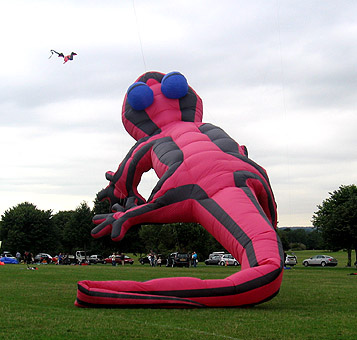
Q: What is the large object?
A: Lizard.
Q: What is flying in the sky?
A: Kite.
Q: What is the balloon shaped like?
A: A large lizard.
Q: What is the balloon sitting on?
A: The grass.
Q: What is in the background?
A: Cars.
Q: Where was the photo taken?
A: Field.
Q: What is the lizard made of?
A: Balloon.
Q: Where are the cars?
A: Field.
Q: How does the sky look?
A: Cloudy.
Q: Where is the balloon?
A: On grass.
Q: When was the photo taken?
A: During a celebration.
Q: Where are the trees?
A: Background.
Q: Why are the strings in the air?
A: Flying kites.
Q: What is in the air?
A: Kites.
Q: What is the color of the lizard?
A: Black and red.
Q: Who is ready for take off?
A: The red lizard.